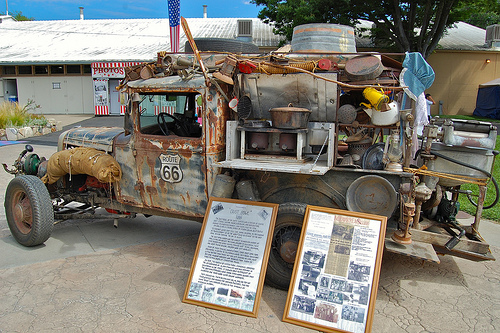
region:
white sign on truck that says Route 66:
[158, 152, 182, 183]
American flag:
[168, 0, 179, 52]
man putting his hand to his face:
[423, 93, 435, 120]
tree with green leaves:
[252, 0, 497, 56]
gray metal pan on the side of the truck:
[346, 173, 396, 218]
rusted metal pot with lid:
[270, 102, 310, 127]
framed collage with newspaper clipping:
[282, 203, 386, 330]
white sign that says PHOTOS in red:
[91, 68, 123, 78]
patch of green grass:
[428, 113, 498, 223]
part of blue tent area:
[472, 80, 498, 120]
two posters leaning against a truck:
[181, 188, 391, 330]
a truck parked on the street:
[8, 40, 488, 275]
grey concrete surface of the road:
[86, 269, 145, 319]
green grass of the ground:
[461, 181, 491, 216]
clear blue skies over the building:
[91, 0, 157, 17]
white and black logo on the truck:
[155, 150, 188, 186]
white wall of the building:
[37, 80, 86, 109]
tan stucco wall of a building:
[439, 62, 474, 103]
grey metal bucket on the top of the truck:
[284, 21, 372, 63]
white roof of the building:
[18, 18, 153, 59]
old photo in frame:
[346, 261, 371, 281]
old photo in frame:
[301, 248, 326, 270]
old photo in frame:
[299, 263, 319, 282]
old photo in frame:
[296, 278, 317, 298]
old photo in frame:
[290, 293, 314, 314]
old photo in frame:
[314, 299, 342, 324]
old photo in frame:
[338, 300, 363, 322]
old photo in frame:
[314, 286, 344, 303]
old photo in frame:
[317, 276, 330, 287]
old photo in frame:
[330, 278, 354, 293]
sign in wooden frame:
[163, 197, 284, 323]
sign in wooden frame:
[278, 202, 405, 332]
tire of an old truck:
[1, 173, 57, 250]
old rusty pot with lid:
[262, 97, 312, 132]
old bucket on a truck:
[336, 168, 411, 225]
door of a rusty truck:
[132, 83, 204, 220]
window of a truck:
[137, 91, 204, 136]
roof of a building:
[0, 10, 278, 60]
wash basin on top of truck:
[285, 17, 367, 62]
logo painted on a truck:
[155, 148, 188, 188]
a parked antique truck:
[0, 41, 481, 263]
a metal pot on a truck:
[278, 98, 309, 129]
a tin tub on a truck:
[342, 167, 405, 216]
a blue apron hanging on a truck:
[395, 41, 440, 109]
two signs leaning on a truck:
[173, 172, 395, 332]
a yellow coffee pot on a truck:
[359, 78, 389, 113]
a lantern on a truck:
[219, 46, 242, 92]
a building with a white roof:
[32, 18, 142, 124]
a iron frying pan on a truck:
[337, 46, 394, 85]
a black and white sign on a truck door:
[154, 151, 189, 184]